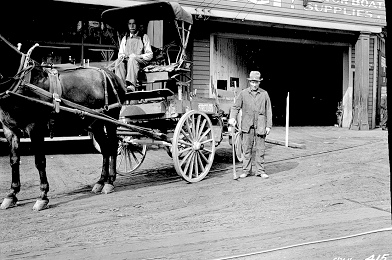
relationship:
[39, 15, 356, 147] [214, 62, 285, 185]
picture of old man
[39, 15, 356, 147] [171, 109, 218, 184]
photo of large spoked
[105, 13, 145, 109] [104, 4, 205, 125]
man in carriage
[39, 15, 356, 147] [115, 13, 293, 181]
picture of two men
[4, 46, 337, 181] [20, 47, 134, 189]
black and white picture of horse in harness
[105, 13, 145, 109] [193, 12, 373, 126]
man standing in front of store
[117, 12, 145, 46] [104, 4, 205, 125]
unsmiling man carriage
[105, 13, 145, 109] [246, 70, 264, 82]
man with hat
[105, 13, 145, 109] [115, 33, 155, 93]
man with overalls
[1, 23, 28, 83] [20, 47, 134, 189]
part of a horse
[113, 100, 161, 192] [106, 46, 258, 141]
wheel of a wagon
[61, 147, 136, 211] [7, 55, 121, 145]
hoof of a horse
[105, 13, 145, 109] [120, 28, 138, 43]
man's shirt collar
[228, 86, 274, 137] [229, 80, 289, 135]
jacket old gray jacket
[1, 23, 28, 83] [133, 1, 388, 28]
part of sign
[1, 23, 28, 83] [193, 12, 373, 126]
part of building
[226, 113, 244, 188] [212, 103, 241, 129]
cane in man's hand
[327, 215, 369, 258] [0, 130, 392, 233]
line on road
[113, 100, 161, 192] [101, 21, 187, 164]
wheel on carraige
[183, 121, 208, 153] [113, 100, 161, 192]
spokes in wheel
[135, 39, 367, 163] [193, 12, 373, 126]
entrance on building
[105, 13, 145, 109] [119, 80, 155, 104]
man wearing shoes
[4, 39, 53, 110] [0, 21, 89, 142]
reins around horse's neck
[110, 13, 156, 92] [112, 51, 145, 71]
man wearing jeans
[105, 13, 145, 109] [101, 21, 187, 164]
seat across carraige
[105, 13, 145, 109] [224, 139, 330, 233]
man on road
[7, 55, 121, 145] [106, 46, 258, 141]
horse hitched to wagon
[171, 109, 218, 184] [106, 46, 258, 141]
large spoked wheel wagon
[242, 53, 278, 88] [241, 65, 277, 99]
hat on head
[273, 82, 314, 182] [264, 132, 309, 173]
post sticking out ground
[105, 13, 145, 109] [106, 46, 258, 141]
man on wagon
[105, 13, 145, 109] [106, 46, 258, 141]
man near wagon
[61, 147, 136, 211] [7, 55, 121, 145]
hoof of horse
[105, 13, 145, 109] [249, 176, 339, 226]
man standing in street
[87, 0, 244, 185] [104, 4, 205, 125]
wagon covered carriage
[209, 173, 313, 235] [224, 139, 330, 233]
unpaved dirt road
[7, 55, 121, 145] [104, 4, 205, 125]
horse drawn carriage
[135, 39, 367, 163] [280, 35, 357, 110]
large business entryway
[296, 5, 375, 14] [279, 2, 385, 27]
painted business sign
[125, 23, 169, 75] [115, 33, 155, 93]
pair of overalls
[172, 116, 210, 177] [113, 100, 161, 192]
large spoked wagon wheel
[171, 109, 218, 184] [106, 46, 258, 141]
large spoked on wagon